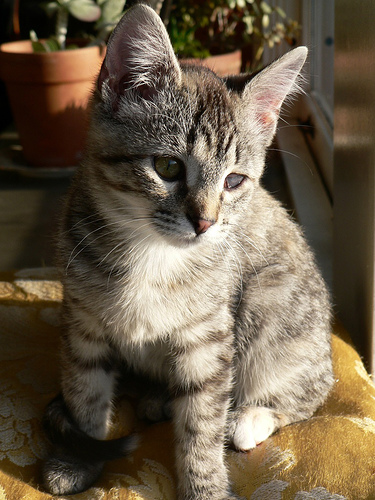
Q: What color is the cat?
A: Black, Gray and White.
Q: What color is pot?
A: Brown.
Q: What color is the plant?
A: Green.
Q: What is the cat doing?
A: Sitting down.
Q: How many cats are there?
A: One.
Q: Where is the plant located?
A: Behind the cat.